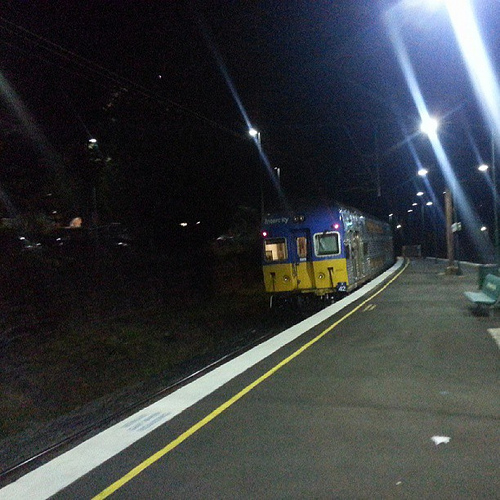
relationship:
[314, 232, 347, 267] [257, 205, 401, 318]
window of train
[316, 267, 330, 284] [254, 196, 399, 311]
headlight of train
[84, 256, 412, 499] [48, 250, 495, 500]
stripe on platform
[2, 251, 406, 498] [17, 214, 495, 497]
stripe on platform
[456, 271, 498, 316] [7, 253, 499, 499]
bench on platform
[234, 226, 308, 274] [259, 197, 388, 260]
light on area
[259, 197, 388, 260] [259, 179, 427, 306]
area of train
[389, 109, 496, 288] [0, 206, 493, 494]
street lights in area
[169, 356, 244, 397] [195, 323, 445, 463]
line on platform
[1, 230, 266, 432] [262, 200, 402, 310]
grass to left of train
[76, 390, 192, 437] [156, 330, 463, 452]
edge of road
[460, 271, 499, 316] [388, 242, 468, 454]
bench on train platform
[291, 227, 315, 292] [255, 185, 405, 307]
door on train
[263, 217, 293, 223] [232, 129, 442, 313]
writing on train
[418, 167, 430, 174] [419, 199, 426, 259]
light on post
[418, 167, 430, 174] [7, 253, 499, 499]
light on platform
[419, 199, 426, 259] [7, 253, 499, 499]
post on platform